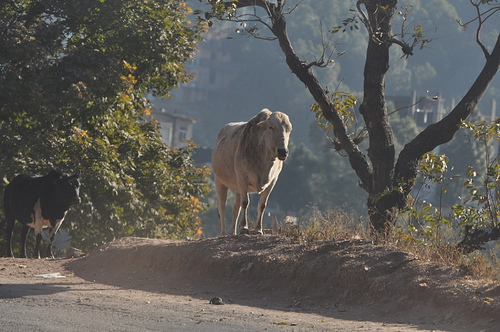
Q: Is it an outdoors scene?
A: Yes, it is outdoors.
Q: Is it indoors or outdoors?
A: It is outdoors.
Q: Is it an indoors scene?
A: No, it is outdoors.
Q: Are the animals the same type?
A: Yes, all the animals are cows.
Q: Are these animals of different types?
A: No, all the animals are cows.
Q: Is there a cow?
A: Yes, there is a cow.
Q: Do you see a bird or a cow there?
A: Yes, there is a cow.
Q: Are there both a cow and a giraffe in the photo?
A: No, there is a cow but no giraffes.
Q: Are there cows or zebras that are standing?
A: Yes, the cow is standing.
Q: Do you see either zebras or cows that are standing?
A: Yes, the cow is standing.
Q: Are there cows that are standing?
A: Yes, there is a cow that is standing.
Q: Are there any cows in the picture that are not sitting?
A: Yes, there is a cow that is standing.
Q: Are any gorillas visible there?
A: No, there are no gorillas.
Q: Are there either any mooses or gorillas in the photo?
A: No, there are no gorillas or mooses.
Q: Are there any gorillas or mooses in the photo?
A: No, there are no gorillas or mooses.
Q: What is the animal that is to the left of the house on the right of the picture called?
A: The animal is a cow.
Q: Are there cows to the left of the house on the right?
A: Yes, there is a cow to the left of the house.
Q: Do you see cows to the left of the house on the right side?
A: Yes, there is a cow to the left of the house.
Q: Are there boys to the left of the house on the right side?
A: No, there is a cow to the left of the house.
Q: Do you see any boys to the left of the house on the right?
A: No, there is a cow to the left of the house.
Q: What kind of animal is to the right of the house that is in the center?
A: The animal is a cow.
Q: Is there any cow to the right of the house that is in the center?
A: Yes, there is a cow to the right of the house.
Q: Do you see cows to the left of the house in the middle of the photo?
A: No, the cow is to the right of the house.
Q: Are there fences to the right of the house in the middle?
A: No, there is a cow to the right of the house.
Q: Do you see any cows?
A: Yes, there is a cow.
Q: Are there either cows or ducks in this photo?
A: Yes, there is a cow.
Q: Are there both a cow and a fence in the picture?
A: No, there is a cow but no fences.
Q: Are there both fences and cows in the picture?
A: No, there is a cow but no fences.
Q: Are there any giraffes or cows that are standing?
A: Yes, the cow is standing.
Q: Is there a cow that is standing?
A: Yes, there is a cow that is standing.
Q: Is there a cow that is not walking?
A: Yes, there is a cow that is standing.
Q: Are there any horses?
A: No, there are no horses.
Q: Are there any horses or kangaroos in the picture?
A: No, there are no horses or kangaroos.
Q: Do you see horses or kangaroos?
A: No, there are no horses or kangaroos.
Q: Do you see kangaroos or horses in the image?
A: No, there are no horses or kangaroos.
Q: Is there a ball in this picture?
A: No, there are no balls.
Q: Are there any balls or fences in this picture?
A: No, there are no balls or fences.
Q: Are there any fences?
A: No, there are no fences.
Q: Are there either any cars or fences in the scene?
A: No, there are no fences or cars.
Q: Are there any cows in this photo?
A: Yes, there is a cow.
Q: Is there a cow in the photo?
A: Yes, there is a cow.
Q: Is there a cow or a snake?
A: Yes, there is a cow.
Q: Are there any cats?
A: No, there are no cats.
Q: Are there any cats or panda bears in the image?
A: No, there are no cats or panda bears.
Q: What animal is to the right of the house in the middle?
A: The animal is a cow.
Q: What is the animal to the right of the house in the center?
A: The animal is a cow.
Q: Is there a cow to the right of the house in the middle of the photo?
A: Yes, there is a cow to the right of the house.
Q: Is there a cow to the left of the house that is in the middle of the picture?
A: No, the cow is to the right of the house.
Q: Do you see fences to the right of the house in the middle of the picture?
A: No, there is a cow to the right of the house.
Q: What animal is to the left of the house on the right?
A: The animal is a cow.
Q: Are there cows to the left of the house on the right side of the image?
A: Yes, there is a cow to the left of the house.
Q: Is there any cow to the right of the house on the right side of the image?
A: No, the cow is to the left of the house.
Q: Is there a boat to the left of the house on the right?
A: No, there is a cow to the left of the house.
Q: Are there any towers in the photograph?
A: No, there are no towers.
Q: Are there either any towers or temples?
A: No, there are no towers or temples.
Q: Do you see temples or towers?
A: No, there are no towers or temples.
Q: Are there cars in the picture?
A: No, there are no cars.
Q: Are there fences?
A: No, there are no fences.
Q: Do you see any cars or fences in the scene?
A: No, there are no fences or cars.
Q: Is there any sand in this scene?
A: Yes, there is sand.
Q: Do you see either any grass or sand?
A: Yes, there is sand.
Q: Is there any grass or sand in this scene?
A: Yes, there is sand.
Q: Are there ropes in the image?
A: No, there are no ropes.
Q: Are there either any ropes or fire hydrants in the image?
A: No, there are no ropes or fire hydrants.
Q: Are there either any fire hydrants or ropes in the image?
A: No, there are no ropes or fire hydrants.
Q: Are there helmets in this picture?
A: No, there are no helmets.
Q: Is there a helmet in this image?
A: No, there are no helmets.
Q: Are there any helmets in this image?
A: No, there are no helmets.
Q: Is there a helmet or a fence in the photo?
A: No, there are no helmets or fences.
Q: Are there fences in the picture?
A: No, there are no fences.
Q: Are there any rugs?
A: No, there are no rugs.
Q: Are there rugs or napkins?
A: No, there are no rugs or napkins.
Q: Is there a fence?
A: No, there are no fences.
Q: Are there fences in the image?
A: No, there are no fences.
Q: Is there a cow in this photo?
A: Yes, there is a cow.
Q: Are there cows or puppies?
A: Yes, there is a cow.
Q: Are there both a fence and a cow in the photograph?
A: No, there is a cow but no fences.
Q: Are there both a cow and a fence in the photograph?
A: No, there is a cow but no fences.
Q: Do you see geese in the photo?
A: No, there are no geese.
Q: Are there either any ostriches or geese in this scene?
A: No, there are no geese or ostriches.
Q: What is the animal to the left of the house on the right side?
A: The animal is a cow.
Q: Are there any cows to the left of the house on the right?
A: Yes, there is a cow to the left of the house.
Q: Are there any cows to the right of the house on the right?
A: No, the cow is to the left of the house.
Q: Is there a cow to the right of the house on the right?
A: No, the cow is to the left of the house.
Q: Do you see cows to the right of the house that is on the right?
A: No, the cow is to the left of the house.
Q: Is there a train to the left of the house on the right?
A: No, there is a cow to the left of the house.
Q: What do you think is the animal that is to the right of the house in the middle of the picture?
A: The animal is a cow.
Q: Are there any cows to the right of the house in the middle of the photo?
A: Yes, there is a cow to the right of the house.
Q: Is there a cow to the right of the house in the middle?
A: Yes, there is a cow to the right of the house.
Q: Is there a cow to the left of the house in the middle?
A: No, the cow is to the right of the house.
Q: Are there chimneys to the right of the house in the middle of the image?
A: No, there is a cow to the right of the house.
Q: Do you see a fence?
A: No, there are no fences.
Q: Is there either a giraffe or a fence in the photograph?
A: No, there are no fences or giraffes.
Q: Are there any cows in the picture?
A: Yes, there are cows.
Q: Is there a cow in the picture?
A: Yes, there are cows.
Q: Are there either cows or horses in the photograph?
A: Yes, there are cows.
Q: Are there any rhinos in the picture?
A: No, there are no rhinos.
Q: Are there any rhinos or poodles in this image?
A: No, there are no rhinos or poodles.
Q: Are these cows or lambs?
A: These are cows.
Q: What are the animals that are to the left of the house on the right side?
A: The animals are cows.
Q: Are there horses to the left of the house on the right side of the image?
A: No, there are cows to the left of the house.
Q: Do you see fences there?
A: No, there are no fences.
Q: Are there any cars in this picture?
A: No, there are no cars.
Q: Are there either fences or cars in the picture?
A: No, there are no cars or fences.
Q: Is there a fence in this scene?
A: No, there are no fences.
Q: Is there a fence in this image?
A: No, there are no fences.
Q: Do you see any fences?
A: No, there are no fences.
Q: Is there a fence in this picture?
A: No, there are no fences.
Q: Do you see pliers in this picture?
A: No, there are no pliers.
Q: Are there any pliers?
A: No, there are no pliers.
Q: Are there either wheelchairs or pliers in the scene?
A: No, there are no pliers or wheelchairs.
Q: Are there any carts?
A: No, there are no carts.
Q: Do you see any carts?
A: No, there are no carts.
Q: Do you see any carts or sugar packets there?
A: No, there are no carts or sugar packets.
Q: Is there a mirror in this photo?
A: No, there are no mirrors.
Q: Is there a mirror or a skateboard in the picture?
A: No, there are no mirrors or skateboards.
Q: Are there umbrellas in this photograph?
A: No, there are no umbrellas.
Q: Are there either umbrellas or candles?
A: No, there are no umbrellas or candles.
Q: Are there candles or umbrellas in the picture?
A: No, there are no umbrellas or candles.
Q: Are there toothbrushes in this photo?
A: No, there are no toothbrushes.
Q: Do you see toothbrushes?
A: No, there are no toothbrushes.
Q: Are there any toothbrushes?
A: No, there are no toothbrushes.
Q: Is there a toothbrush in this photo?
A: No, there are no toothbrushes.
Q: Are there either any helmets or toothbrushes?
A: No, there are no toothbrushes or helmets.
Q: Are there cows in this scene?
A: Yes, there is a cow.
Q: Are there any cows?
A: Yes, there is a cow.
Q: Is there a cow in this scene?
A: Yes, there is a cow.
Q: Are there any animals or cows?
A: Yes, there is a cow.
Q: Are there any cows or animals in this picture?
A: Yes, there is a cow.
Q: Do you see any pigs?
A: No, there are no pigs.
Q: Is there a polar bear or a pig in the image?
A: No, there are no pigs or polar bears.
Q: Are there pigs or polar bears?
A: No, there are no pigs or polar bears.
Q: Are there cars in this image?
A: No, there are no cars.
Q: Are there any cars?
A: No, there are no cars.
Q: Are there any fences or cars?
A: No, there are no cars or fences.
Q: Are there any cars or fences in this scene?
A: No, there are no cars or fences.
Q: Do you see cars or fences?
A: No, there are no cars or fences.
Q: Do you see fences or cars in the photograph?
A: No, there are no cars or fences.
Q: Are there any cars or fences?
A: No, there are no cars or fences.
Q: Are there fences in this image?
A: No, there are no fences.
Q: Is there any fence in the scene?
A: No, there are no fences.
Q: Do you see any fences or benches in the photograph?
A: No, there are no fences or benches.